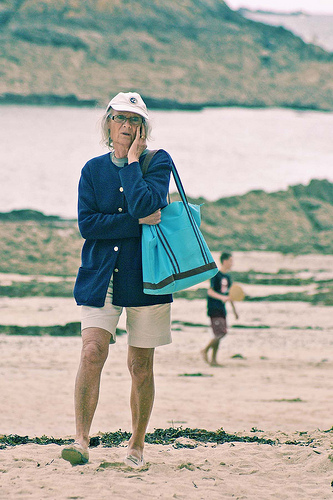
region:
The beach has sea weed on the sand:
[4, 420, 324, 462]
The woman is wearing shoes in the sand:
[60, 441, 146, 470]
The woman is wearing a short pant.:
[62, 264, 174, 346]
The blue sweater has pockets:
[70, 153, 179, 311]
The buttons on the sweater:
[107, 180, 123, 277]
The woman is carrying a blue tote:
[133, 145, 225, 295]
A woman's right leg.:
[67, 322, 113, 446]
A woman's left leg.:
[127, 345, 155, 462]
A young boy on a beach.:
[201, 248, 248, 369]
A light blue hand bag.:
[141, 152, 221, 301]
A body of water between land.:
[1, 111, 329, 218]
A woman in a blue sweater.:
[73, 150, 176, 310]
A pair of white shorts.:
[79, 276, 174, 347]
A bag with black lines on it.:
[140, 198, 217, 296]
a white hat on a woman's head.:
[99, 89, 155, 126]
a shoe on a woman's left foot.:
[124, 453, 151, 477]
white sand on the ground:
[106, 458, 112, 471]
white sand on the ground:
[182, 476, 190, 482]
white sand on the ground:
[225, 469, 235, 475]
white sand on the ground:
[254, 478, 262, 485]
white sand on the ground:
[218, 454, 224, 460]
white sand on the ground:
[117, 464, 127, 473]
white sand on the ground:
[73, 473, 91, 482]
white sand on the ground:
[34, 465, 49, 474]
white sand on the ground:
[312, 481, 315, 487]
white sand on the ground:
[209, 455, 220, 464]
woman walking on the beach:
[61, 89, 224, 469]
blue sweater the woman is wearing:
[73, 148, 185, 304]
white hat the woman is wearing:
[105, 90, 145, 118]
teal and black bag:
[140, 147, 216, 291]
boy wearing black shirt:
[204, 249, 247, 366]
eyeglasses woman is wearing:
[107, 111, 140, 125]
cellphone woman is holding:
[134, 121, 143, 140]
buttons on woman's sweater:
[112, 174, 126, 273]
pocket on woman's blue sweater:
[73, 266, 101, 295]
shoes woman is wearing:
[63, 442, 142, 471]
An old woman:
[79, 86, 208, 340]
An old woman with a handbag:
[69, 73, 214, 436]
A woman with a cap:
[70, 72, 215, 414]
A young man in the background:
[200, 235, 243, 367]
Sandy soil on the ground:
[222, 384, 303, 434]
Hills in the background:
[245, 185, 306, 249]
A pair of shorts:
[71, 272, 170, 350]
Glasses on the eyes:
[108, 109, 154, 125]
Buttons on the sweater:
[113, 179, 132, 277]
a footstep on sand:
[184, 475, 203, 486]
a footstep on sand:
[149, 477, 166, 484]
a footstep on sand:
[201, 449, 216, 463]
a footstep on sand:
[257, 445, 271, 464]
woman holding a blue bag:
[134, 144, 214, 299]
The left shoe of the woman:
[61, 443, 94, 468]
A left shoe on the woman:
[58, 441, 92, 465]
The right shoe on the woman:
[119, 451, 149, 471]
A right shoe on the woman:
[123, 447, 152, 472]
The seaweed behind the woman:
[4, 419, 287, 455]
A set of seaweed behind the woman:
[4, 421, 282, 460]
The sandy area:
[1, 323, 322, 492]